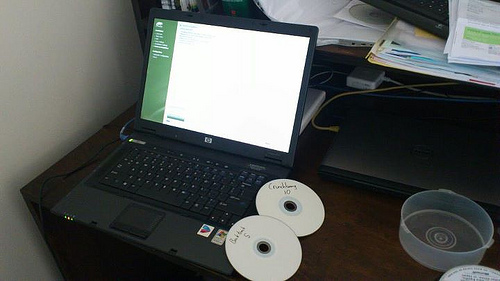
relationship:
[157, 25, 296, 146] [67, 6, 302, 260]
screen of laptop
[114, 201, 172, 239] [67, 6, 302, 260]
trackpad on laptop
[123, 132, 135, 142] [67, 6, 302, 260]
lights on laptop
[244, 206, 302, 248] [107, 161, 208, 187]
discs on keyboard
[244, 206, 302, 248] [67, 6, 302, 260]
discs next to laptop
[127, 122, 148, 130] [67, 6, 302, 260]
logo on laptop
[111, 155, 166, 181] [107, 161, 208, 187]
keys on keyboard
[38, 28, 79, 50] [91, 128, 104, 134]
wall next to table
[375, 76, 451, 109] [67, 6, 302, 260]
cords near laptop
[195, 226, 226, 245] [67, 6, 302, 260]
stickers on laptop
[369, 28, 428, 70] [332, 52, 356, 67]
papers on shelf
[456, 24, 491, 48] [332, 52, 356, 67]
books on shelf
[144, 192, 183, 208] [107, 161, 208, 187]
space bar of keyboard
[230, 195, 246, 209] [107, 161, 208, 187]
enter key on keyboard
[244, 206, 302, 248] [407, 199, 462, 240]
discs in cd case